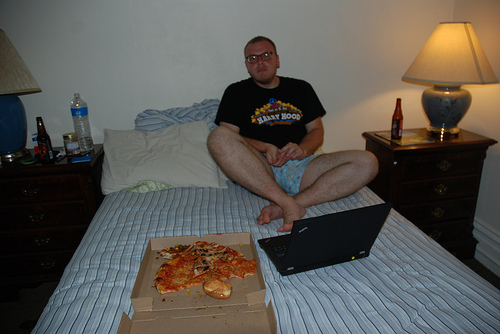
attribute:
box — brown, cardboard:
[132, 231, 274, 333]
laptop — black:
[258, 195, 390, 286]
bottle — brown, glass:
[36, 117, 55, 162]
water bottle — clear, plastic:
[69, 94, 95, 152]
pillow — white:
[99, 128, 224, 189]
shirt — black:
[214, 78, 331, 151]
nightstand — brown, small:
[371, 131, 496, 264]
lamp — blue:
[402, 21, 495, 134]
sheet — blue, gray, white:
[102, 184, 246, 231]